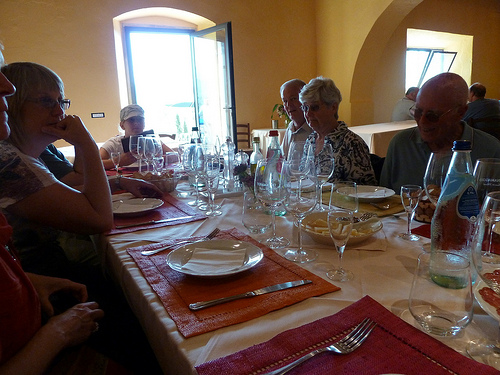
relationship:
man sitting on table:
[381, 72, 500, 194] [103, 157, 497, 373]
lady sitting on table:
[298, 75, 375, 192] [103, 157, 497, 373]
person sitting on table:
[273, 73, 317, 178] [103, 157, 497, 373]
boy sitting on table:
[99, 104, 174, 162] [103, 157, 497, 373]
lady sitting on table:
[0, 61, 115, 302] [103, 157, 497, 373]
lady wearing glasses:
[0, 61, 115, 302] [32, 96, 74, 111]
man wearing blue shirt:
[381, 72, 500, 194] [377, 119, 499, 196]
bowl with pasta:
[291, 205, 383, 243] [308, 213, 370, 233]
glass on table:
[404, 240, 479, 346] [207, 193, 497, 344]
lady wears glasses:
[298, 75, 375, 192] [298, 97, 340, 112]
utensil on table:
[185, 276, 313, 312] [68, 154, 499, 374]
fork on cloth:
[261, 310, 380, 373] [191, 291, 499, 371]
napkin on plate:
[176, 248, 251, 274] [161, 230, 266, 280]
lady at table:
[298, 75, 376, 182] [115, 200, 442, 371]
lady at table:
[2, 59, 115, 233] [349, 253, 408, 300]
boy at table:
[99, 104, 174, 162] [115, 200, 442, 371]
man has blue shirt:
[381, 72, 500, 194] [377, 119, 499, 196]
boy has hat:
[99, 104, 174, 162] [99, 100, 158, 125]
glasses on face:
[22, 94, 72, 111] [28, 78, 72, 145]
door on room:
[121, 22, 239, 159] [1, 3, 496, 370]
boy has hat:
[96, 102, 173, 162] [117, 102, 148, 121]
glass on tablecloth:
[397, 185, 422, 239] [97, 153, 495, 372]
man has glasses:
[377, 74, 498, 202] [408, 107, 455, 118]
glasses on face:
[408, 107, 455, 118] [412, 95, 447, 147]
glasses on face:
[299, 104, 328, 111] [295, 93, 338, 131]